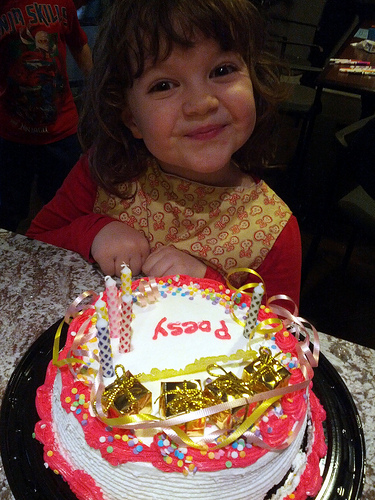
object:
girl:
[24, 0, 302, 313]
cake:
[34, 272, 331, 499]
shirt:
[1, 3, 88, 147]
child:
[0, 1, 96, 235]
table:
[0, 225, 375, 498]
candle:
[242, 277, 267, 339]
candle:
[119, 290, 133, 351]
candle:
[120, 261, 132, 299]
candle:
[104, 273, 118, 336]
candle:
[95, 316, 115, 378]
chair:
[250, 81, 326, 201]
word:
[151, 314, 232, 342]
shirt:
[26, 142, 305, 318]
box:
[100, 368, 152, 415]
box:
[159, 379, 200, 431]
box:
[203, 371, 256, 439]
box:
[244, 351, 290, 399]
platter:
[1, 286, 368, 499]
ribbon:
[263, 293, 327, 371]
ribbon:
[220, 265, 274, 342]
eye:
[146, 77, 182, 95]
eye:
[206, 60, 238, 79]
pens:
[329, 56, 374, 77]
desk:
[321, 0, 375, 92]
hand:
[141, 246, 208, 280]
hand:
[91, 218, 151, 279]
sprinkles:
[130, 287, 247, 315]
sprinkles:
[60, 382, 289, 473]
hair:
[78, 7, 299, 201]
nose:
[181, 78, 222, 119]